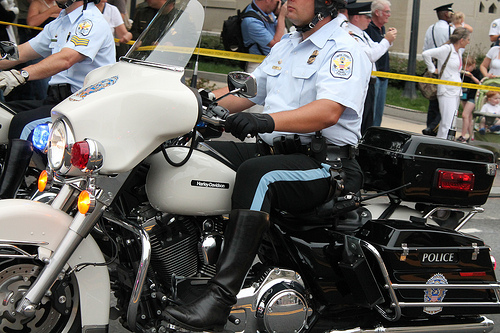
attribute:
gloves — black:
[193, 92, 273, 144]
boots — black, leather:
[156, 207, 356, 307]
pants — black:
[190, 141, 367, 235]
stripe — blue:
[247, 155, 339, 209]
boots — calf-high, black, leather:
[150, 201, 276, 331]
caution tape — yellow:
[89, 21, 496, 92]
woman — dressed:
[422, 26, 470, 166]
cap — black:
[433, 2, 451, 11]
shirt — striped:
[33, 6, 124, 91]